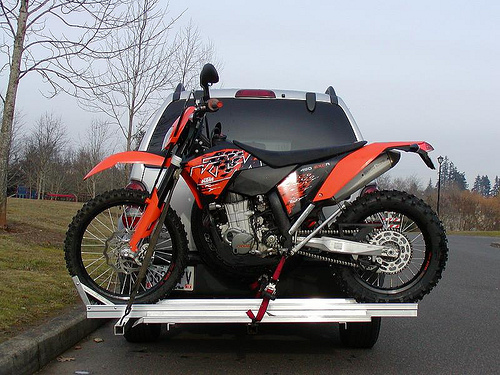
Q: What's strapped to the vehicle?
A: Motorcycle.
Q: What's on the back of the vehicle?
A: Motorcycle.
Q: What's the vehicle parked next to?
A: Curb.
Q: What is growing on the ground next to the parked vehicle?
A: Grass.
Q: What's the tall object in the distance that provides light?
A: Street light.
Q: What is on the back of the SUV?
A: A motorcycle.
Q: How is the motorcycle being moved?
A: By the SUV.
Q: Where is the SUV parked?
A: On the side of the road by a grass field.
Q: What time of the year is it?
A: Late fall.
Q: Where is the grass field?
A: To the left of the vehicle.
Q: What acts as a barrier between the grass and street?
A: A cement curb.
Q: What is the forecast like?
A: Cloudy with no sun.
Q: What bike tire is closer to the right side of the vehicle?
A: The back tire.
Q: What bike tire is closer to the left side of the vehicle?
A: The front tire.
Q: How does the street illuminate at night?
A: By the light post in the background.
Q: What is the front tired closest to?
A: The curb.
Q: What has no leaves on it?
A: The trees.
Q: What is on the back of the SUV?
A: A motorcycle.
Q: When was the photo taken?
A: During the day.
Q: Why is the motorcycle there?
A: For a person to drive later.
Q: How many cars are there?
A: One.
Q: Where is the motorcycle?
A: On the car.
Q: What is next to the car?
A: A tree.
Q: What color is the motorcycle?
A: Red and black.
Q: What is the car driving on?
A: The street.